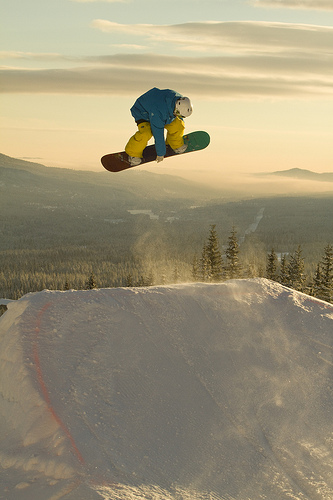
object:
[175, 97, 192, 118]
helmet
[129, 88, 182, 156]
coat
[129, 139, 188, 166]
shoes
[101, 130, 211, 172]
board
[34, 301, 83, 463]
line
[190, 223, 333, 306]
trees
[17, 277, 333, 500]
ramp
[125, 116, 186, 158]
pants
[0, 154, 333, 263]
mountains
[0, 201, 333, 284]
valley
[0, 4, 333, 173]
sky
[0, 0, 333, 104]
clouds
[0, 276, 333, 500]
snow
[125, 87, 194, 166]
boy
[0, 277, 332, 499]
path